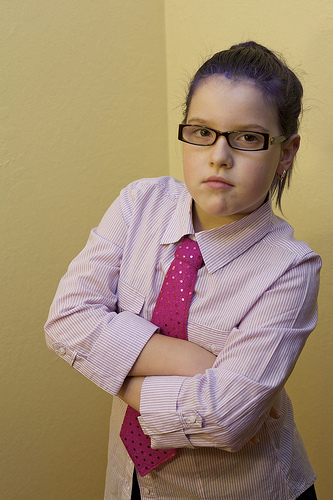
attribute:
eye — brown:
[237, 133, 258, 144]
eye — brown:
[192, 129, 210, 138]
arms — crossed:
[52, 308, 235, 416]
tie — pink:
[119, 236, 204, 471]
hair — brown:
[181, 42, 308, 215]